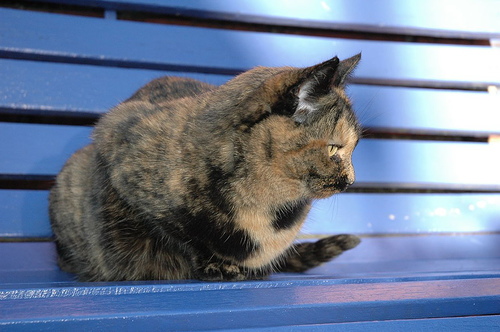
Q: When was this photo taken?
A: Day time.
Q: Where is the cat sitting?
A: On the bench.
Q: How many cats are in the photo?
A: One.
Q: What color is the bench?
A: Blue.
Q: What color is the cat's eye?
A: Yellow.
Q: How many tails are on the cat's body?
A: One.